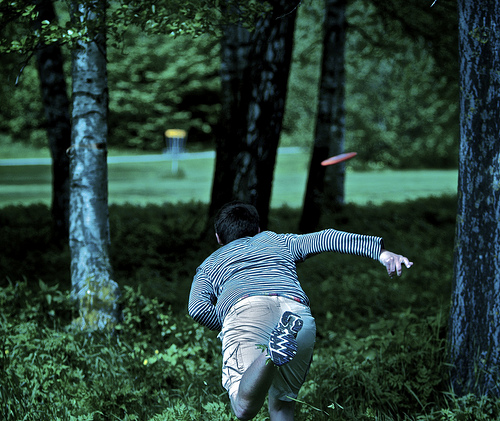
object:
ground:
[2, 147, 497, 417]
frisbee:
[320, 151, 357, 166]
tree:
[9, 12, 240, 343]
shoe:
[268, 311, 303, 363]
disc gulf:
[164, 127, 187, 175]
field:
[106, 147, 215, 205]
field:
[343, 156, 458, 206]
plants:
[53, 354, 141, 398]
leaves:
[6, 278, 221, 419]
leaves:
[312, 275, 454, 419]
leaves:
[2, 203, 67, 282]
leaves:
[110, 198, 202, 268]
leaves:
[354, 196, 456, 270]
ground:
[7, 198, 458, 419]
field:
[0, 148, 498, 418]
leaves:
[0, 0, 275, 57]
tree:
[66, 0, 123, 341]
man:
[167, 194, 452, 419]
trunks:
[211, 24, 293, 167]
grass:
[1, 137, 493, 419]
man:
[181, 200, 417, 417]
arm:
[279, 227, 381, 263]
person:
[206, 204, 269, 299]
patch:
[379, 359, 427, 412]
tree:
[33, 32, 144, 354]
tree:
[303, 23, 358, 221]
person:
[184, 200, 419, 420]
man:
[197, 194, 293, 285]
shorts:
[215, 299, 283, 365]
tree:
[451, 0, 498, 388]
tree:
[61, 3, 125, 329]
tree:
[313, 3, 355, 231]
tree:
[218, 10, 292, 240]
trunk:
[69, 8, 124, 329]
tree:
[0, 1, 277, 331]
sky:
[75, 51, 260, 159]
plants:
[132, 250, 161, 355]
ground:
[89, 349, 232, 410]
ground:
[141, 305, 428, 380]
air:
[65, 106, 216, 204]